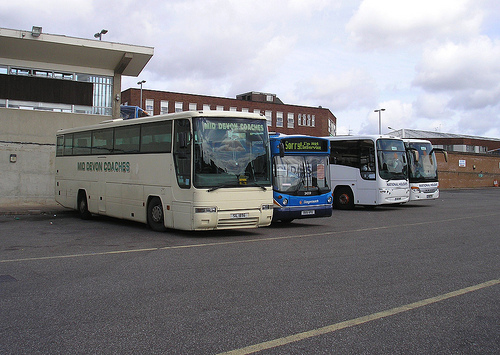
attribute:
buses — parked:
[52, 108, 452, 242]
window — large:
[186, 123, 276, 190]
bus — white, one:
[48, 103, 280, 246]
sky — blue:
[150, 4, 499, 118]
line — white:
[332, 279, 475, 335]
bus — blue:
[275, 123, 340, 224]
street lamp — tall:
[370, 101, 388, 173]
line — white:
[299, 286, 471, 342]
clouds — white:
[410, 35, 499, 102]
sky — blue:
[6, 1, 498, 111]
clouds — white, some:
[243, 9, 471, 81]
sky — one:
[278, 30, 466, 98]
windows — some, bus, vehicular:
[49, 115, 186, 160]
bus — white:
[48, 112, 303, 251]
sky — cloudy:
[128, 11, 468, 141]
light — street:
[369, 98, 392, 148]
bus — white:
[65, 107, 274, 235]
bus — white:
[52, 108, 286, 232]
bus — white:
[328, 130, 420, 208]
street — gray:
[1, 186, 483, 352]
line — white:
[215, 280, 485, 352]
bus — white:
[45, 106, 285, 255]